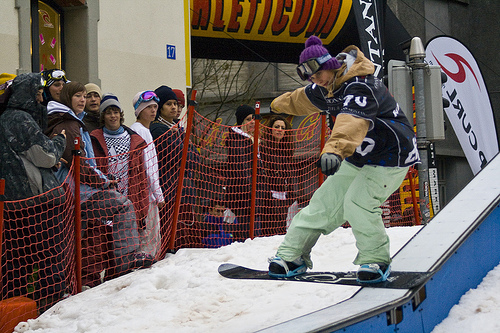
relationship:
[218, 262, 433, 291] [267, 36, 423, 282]
skateboarder under guy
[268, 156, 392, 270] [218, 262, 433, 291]
pants on skateboarder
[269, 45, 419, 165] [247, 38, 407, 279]
jacket on snowboarder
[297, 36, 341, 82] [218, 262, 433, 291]
bonnet on skateboarder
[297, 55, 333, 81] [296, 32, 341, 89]
goggle on head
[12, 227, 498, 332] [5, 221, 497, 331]
snow on ground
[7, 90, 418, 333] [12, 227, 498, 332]
fence by snow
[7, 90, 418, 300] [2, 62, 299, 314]
fence in front of audience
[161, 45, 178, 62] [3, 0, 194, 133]
17 on building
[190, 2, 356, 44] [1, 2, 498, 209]
banner over building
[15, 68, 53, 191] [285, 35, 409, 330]
spectator watching skateboarder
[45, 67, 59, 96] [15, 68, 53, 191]
spectator watching spectator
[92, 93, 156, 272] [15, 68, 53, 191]
people watching spectator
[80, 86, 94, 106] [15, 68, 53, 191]
spectator watching spectator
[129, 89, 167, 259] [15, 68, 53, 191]
people watching spectator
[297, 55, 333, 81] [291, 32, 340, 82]
goggle on bonnet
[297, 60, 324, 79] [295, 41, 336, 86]
goggle on head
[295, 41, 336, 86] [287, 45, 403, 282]
head on guy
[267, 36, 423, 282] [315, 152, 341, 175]
guy wearing glove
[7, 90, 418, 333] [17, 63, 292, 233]
fence separates spectators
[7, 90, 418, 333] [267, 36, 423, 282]
fence separates guy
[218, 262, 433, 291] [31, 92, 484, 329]
skateboarder going down ramp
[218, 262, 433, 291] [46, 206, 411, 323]
skateboarder on snow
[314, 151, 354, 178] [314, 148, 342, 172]
glove on hand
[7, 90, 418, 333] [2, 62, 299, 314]
fence in front of audience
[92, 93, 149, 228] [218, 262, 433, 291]
people watching skateboarder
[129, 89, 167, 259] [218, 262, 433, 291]
people watching skateboarder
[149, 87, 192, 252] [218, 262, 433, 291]
people watching skateboarder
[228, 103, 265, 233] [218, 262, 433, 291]
people watching skateboarder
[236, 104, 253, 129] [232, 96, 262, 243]
hat on top of person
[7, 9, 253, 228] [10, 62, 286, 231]
wall behind audience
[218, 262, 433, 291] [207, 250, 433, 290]
skateboarder on snowboard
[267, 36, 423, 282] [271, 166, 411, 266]
guy wearing pants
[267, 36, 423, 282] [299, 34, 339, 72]
guy wearing hat